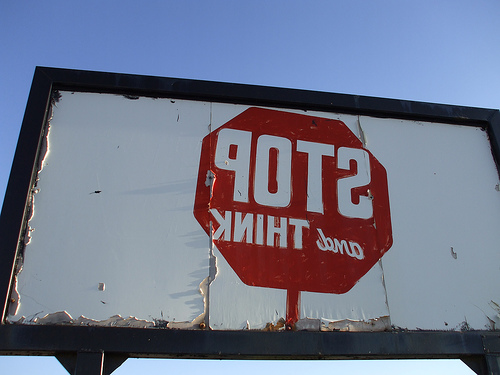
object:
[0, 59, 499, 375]
frame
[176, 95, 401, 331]
stop sign drawing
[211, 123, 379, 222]
stop letters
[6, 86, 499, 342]
paper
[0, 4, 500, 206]
sky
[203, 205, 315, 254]
word think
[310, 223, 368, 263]
word and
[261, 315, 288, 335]
spot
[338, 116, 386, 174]
edge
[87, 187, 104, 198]
dirt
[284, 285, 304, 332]
pole drawing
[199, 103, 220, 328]
line